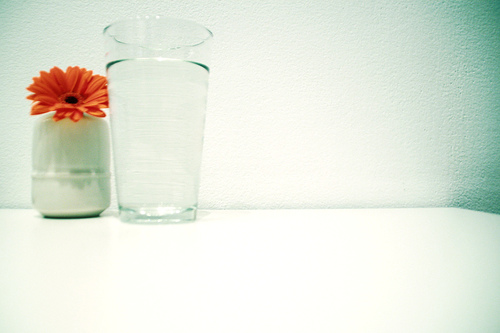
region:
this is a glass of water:
[110, 25, 218, 211]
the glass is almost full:
[108, 35, 210, 209]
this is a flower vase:
[28, 85, 98, 209]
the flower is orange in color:
[37, 69, 98, 112]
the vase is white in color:
[35, 128, 102, 205]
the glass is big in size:
[110, 30, 210, 212]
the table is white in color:
[0, 226, 498, 331]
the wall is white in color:
[225, 28, 472, 192]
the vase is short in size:
[29, 123, 106, 213]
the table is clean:
[2, 228, 446, 329]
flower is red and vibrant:
[25, 62, 123, 122]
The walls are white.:
[7, 13, 489, 332]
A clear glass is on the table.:
[107, 16, 252, 241]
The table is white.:
[52, 211, 366, 310]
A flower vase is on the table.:
[35, 105, 106, 213]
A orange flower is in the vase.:
[22, 58, 132, 178]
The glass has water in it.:
[107, 23, 235, 264]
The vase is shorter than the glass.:
[14, 10, 268, 299]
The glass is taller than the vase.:
[101, 40, 218, 235]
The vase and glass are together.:
[21, 19, 203, 271]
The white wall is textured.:
[248, 9, 483, 220]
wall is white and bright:
[238, 69, 478, 228]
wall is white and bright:
[251, 95, 376, 211]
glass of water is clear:
[113, 17, 200, 238]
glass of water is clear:
[88, 13, 270, 270]